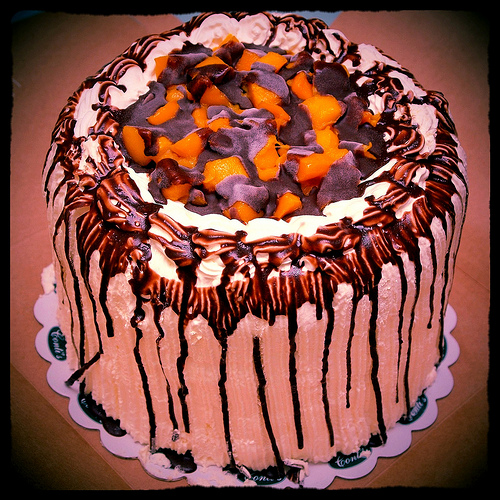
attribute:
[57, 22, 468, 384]
cake — section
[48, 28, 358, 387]
cake — section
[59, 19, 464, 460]
cake — section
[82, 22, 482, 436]
cake — section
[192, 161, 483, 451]
cake — section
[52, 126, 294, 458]
cake — section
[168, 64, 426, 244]
cake — section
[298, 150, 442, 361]
cake — section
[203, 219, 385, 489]
cake — section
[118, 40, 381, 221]
icing — brown, orange, purple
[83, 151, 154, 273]
sauce — chocolate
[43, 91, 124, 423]
icing — white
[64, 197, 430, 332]
sauce — chocolate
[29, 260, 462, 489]
base — white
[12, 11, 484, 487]
table — brown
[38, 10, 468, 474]
cake — white, ice cream, one tier, tall, big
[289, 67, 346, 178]
slices — mango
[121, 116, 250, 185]
slices — mango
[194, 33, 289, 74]
slices — mango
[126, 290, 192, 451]
lines — chocolate, syrup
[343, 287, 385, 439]
lines — syrup, chocolate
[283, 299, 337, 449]
lines — chocolate, syrup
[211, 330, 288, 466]
lines — syrup, chocolate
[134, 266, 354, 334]
syrup — chocolate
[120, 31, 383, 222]
fruit — orange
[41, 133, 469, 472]
icing — white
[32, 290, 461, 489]
cardboard — white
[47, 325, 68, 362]
circle — black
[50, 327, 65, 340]
letter — white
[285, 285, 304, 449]
chocolate — dripping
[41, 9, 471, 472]
syrup — chocolate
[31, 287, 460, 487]
plate — white, round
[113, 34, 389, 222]
top — dark, orange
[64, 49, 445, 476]
cake — wooden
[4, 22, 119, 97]
table — brown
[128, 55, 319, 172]
food — orange, sliced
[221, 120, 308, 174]
chocolate — sliced, dark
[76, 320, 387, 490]
syrup — black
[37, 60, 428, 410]
cake — tall, orange, chocolate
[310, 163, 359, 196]
chocolate — shaved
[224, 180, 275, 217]
chocolate — shaved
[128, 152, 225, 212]
chocolate — shaved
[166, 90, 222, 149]
chocolate — shaved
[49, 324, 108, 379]
chocolate — shaved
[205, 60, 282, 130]
chocolate — shaved